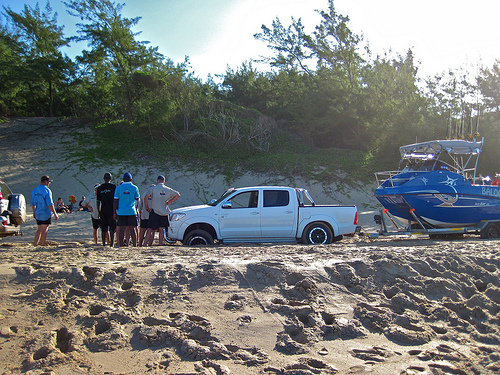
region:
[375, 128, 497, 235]
The boat is blue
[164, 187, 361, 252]
The truck is white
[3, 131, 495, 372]
The sand is tan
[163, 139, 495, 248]
The truck is pulling the boat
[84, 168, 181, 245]
People standing by the truck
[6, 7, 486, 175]
Green bushes growing on the sand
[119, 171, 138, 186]
Man wearing a blue hat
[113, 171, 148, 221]
Man wearing a blue shirt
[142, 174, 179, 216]
Man wearing a tan shirt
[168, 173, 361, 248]
The truck has one of its windows down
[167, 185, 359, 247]
a white pick up truck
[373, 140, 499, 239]
a blue boat on sand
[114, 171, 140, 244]
a man standing on beach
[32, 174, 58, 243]
a man standing on beach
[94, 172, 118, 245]
a man standing on beach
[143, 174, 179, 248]
a man standing on beach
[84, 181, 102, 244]
a man standing on beach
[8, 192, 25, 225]
a covered spare tire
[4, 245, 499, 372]
a sandy beach hill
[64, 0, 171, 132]
large green tree in distance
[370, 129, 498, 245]
a blue and white boat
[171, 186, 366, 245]
a white pickup truck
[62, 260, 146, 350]
footprints in the sand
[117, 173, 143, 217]
a person in a blue shirt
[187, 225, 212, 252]
the front tire of a vehicle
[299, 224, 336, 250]
the rear wheel of a vehicle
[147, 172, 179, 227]
a person with their hand on their hip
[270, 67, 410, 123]
a group of trees with green leaves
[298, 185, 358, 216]
the bed of a pickup truck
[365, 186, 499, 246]
a boat on a trailer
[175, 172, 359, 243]
a white truck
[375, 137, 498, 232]
a blue boat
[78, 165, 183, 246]
a group of people next to a truck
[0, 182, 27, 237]
the back of a car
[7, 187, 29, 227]
a spare tire on the back of a car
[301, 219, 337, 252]
a back tire of a truck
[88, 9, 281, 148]
some trees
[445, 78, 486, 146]
fishing rods on the boat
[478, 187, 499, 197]
letters on the side of the boat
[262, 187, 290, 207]
a window on the truck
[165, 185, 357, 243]
white dual cab truck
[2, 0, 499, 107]
blue sky above the trees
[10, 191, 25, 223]
spare tire of vehicle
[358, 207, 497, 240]
trailer attached to the truck carrying a boat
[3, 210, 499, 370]
flat sandy area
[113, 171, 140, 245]
person in light blue shirt and baseball cap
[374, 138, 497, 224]
front part of blue boat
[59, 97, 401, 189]
green grassy section on the hill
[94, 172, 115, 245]
person in black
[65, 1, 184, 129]
large tree with green leaves